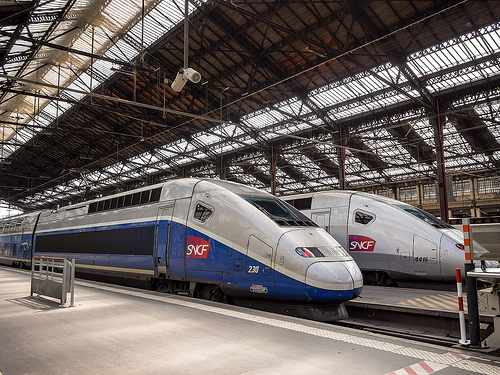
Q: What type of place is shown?
A: It is a train station.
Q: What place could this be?
A: It is a train station.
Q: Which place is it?
A: It is a train station.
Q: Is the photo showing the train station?
A: Yes, it is showing the train station.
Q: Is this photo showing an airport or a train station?
A: It is showing a train station.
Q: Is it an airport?
A: No, it is a train station.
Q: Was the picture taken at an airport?
A: No, the picture was taken in a train station.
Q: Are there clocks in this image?
A: No, there are no clocks.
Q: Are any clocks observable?
A: No, there are no clocks.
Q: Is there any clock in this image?
A: No, there are no clocks.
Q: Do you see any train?
A: Yes, there is a train.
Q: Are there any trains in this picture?
A: Yes, there is a train.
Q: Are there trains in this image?
A: Yes, there is a train.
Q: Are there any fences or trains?
A: Yes, there is a train.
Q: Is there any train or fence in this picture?
A: Yes, there is a train.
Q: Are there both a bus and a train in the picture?
A: No, there is a train but no buses.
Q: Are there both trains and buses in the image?
A: No, there is a train but no buses.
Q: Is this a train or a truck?
A: This is a train.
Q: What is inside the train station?
A: The train is inside the train station.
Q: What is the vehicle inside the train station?
A: The vehicle is a train.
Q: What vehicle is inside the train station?
A: The vehicle is a train.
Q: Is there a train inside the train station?
A: Yes, there is a train inside the train station.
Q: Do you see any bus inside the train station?
A: No, there is a train inside the train station.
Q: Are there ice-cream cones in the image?
A: No, there are no ice-cream cones.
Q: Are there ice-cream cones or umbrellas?
A: No, there are no ice-cream cones or umbrellas.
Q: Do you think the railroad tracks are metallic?
A: Yes, the railroad tracks are metallic.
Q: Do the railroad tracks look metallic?
A: Yes, the railroad tracks are metallic.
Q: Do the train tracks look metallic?
A: Yes, the train tracks are metallic.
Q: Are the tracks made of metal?
A: Yes, the tracks are made of metal.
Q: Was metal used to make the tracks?
A: Yes, the tracks are made of metal.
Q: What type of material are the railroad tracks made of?
A: The railroad tracks are made of metal.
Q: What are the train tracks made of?
A: The railroad tracks are made of metal.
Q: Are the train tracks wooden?
A: No, the train tracks are metallic.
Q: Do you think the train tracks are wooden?
A: No, the train tracks are metallic.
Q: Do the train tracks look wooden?
A: No, the train tracks are metallic.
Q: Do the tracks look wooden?
A: No, the tracks are metallic.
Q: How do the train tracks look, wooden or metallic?
A: The train tracks are metallic.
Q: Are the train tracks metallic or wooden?
A: The train tracks are metallic.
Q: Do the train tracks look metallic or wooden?
A: The train tracks are metallic.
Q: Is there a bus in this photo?
A: No, there are no buses.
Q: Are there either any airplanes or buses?
A: No, there are no buses or airplanes.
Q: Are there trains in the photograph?
A: Yes, there is a train.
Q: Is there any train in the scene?
A: Yes, there is a train.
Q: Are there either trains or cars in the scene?
A: Yes, there is a train.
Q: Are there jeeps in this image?
A: No, there are no jeeps.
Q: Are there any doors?
A: Yes, there is a door.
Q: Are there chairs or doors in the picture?
A: Yes, there is a door.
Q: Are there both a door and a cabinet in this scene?
A: No, there is a door but no cabinets.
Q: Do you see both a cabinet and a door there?
A: No, there is a door but no cabinets.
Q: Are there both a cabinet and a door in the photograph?
A: No, there is a door but no cabinets.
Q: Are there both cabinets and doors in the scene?
A: No, there is a door but no cabinets.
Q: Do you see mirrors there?
A: No, there are no mirrors.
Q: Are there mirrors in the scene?
A: No, there are no mirrors.